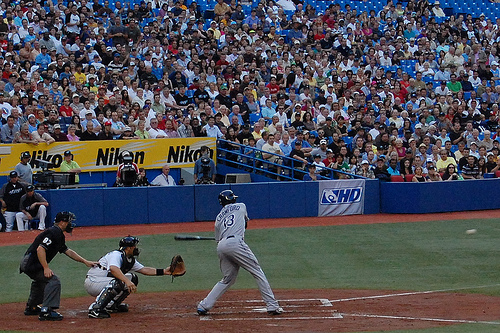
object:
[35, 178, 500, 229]
fence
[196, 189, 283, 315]
baseball player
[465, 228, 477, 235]
ball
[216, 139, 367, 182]
railing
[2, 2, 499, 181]
spectators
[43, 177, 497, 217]
padding